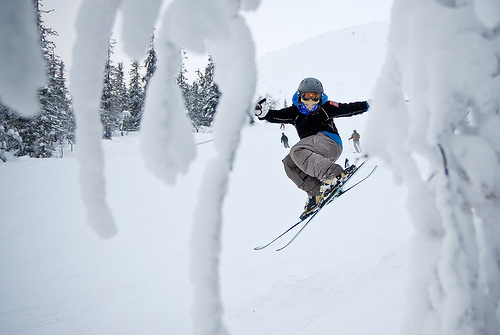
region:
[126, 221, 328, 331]
the leaf is full of snow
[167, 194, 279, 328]
the leaf is full of snow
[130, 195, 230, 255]
the leaf is full of snow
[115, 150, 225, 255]
the leaf is full of snow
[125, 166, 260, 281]
the leaf is full of snow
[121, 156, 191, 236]
the leaf is full of snow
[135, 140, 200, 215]
the leaf is full of snow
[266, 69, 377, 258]
skier jumping in the air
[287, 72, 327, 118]
helmet on the skier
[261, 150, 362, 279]
skis on the skier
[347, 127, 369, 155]
skier on the mountain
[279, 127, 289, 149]
skier on the mountain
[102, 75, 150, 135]
snowy trees in the background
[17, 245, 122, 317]
snow on the mountain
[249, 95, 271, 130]
glove on the skier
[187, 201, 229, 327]
snow on tree branch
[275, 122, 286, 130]
skier on the mountain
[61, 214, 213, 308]
The ground is snow covered.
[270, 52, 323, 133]
She is wearing a helmet.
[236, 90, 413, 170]
She is wearing a black jacket.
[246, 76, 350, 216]
She is wearing tan pants.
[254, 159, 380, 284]
Her skies are long.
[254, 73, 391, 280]
She is jumping.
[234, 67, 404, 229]
She is doing a trick.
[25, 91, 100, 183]
The trees are snow covered.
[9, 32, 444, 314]
She is skiing.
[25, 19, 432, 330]
She is in the mountain.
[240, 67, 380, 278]
a skier doing a trick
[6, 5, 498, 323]
some snow covered branches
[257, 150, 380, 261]
a pair of skis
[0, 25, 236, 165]
some snow covered trees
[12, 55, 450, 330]
a snowy landscape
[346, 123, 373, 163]
a man skiing on his own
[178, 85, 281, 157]
a ski pole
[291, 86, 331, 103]
orange goggles on the skiier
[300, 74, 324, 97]
a grey helmet on the skiier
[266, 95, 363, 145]
a black jacket on the skiier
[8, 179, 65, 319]
this is the ground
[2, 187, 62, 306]
the ground is full of snow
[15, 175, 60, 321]
this is the snow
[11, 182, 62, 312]
the snow is white in color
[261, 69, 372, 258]
this is a man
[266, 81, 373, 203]
the man is in the air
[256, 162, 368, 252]
these are snowboards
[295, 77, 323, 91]
this is a helmet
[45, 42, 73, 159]
these are some trees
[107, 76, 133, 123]
the leaves are covered with snow